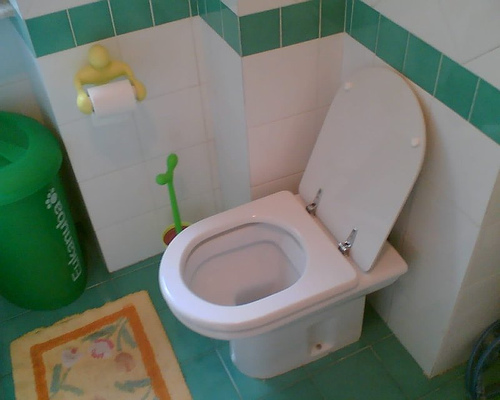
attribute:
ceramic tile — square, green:
[239, 9, 279, 57]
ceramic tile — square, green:
[282, 0, 317, 45]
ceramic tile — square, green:
[220, 6, 241, 53]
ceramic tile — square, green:
[67, 1, 116, 48]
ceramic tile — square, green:
[375, 18, 407, 71]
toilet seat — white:
[261, 258, 353, 296]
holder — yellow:
[70, 43, 140, 122]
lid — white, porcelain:
[306, 49, 411, 259]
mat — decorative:
[47, 321, 175, 393]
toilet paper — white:
[73, 66, 175, 128]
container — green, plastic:
[10, 108, 109, 322]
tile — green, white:
[411, 45, 444, 87]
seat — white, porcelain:
[154, 187, 357, 342]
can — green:
[2, 110, 119, 333]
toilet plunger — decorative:
[153, 151, 195, 247]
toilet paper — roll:
[88, 76, 138, 116]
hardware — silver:
[304, 194, 359, 257]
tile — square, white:
[132, 70, 222, 169]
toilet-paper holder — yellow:
[67, 45, 147, 113]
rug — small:
[13, 297, 184, 399]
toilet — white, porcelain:
[162, 65, 432, 379]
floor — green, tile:
[5, 259, 405, 398]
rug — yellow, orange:
[10, 288, 196, 398]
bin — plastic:
[0, 103, 91, 308]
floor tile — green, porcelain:
[315, 350, 414, 398]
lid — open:
[302, 47, 428, 267]